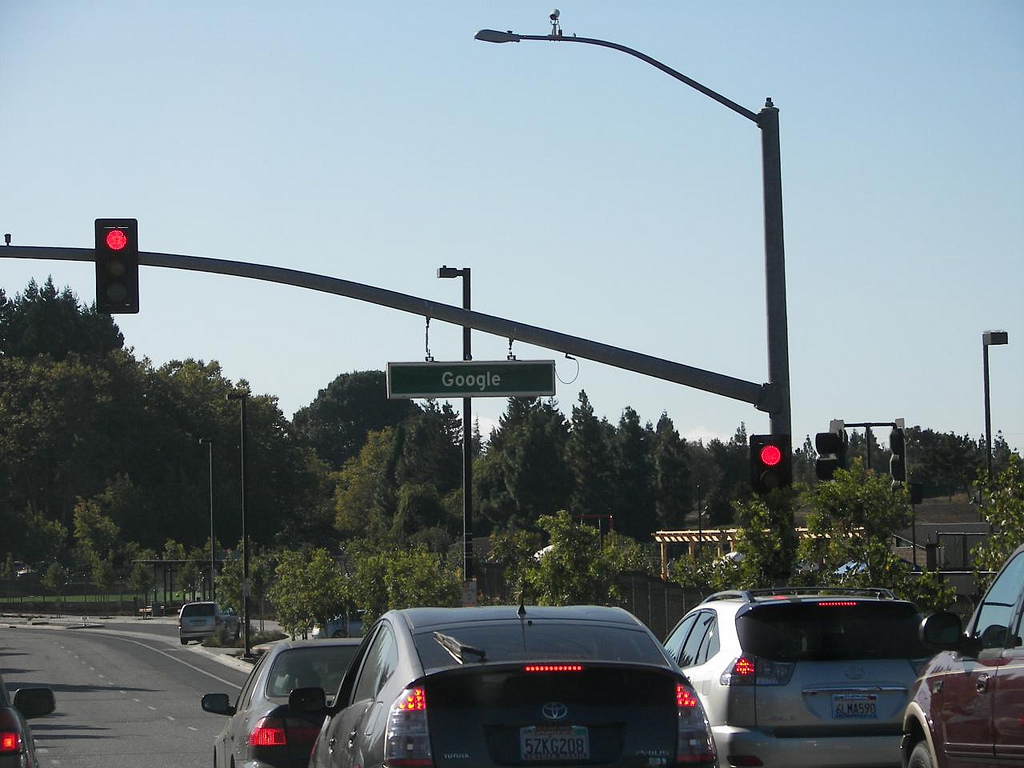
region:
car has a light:
[673, 680, 699, 713]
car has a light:
[526, 661, 584, 678]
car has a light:
[390, 686, 425, 712]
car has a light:
[245, 722, 287, 746]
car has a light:
[381, 712, 433, 766]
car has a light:
[675, 734, 724, 766]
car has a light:
[816, 597, 859, 616]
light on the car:
[510, 654, 574, 677]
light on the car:
[396, 672, 428, 711]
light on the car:
[668, 677, 703, 706]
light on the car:
[722, 654, 755, 680]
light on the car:
[226, 625, 231, 627]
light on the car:
[177, 623, 196, 631]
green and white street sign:
[370, 344, 604, 444]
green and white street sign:
[355, 350, 591, 399]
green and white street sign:
[365, 342, 580, 409]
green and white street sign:
[378, 347, 571, 415]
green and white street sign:
[367, 344, 565, 422]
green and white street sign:
[386, 341, 576, 419]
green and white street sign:
[364, 342, 580, 431]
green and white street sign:
[375, 347, 579, 430]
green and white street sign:
[361, 342, 578, 416]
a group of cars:
[227, 519, 1018, 766]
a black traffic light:
[731, 417, 799, 515]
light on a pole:
[417, 244, 516, 590]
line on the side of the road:
[127, 625, 245, 686]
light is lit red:
[75, 195, 162, 326]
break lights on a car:
[376, 645, 715, 738]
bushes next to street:
[250, 511, 706, 619]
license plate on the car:
[497, 708, 597, 766]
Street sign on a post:
[378, 358, 557, 398]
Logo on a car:
[533, 694, 576, 727]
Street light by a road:
[215, 374, 283, 675]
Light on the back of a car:
[376, 685, 441, 765]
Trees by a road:
[256, 549, 460, 636]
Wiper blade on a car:
[429, 621, 484, 664]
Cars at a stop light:
[221, 599, 709, 761]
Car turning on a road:
[166, 596, 244, 647]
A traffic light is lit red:
[81, 201, 155, 328]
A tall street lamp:
[457, 1, 802, 504]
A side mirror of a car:
[898, 593, 976, 666]